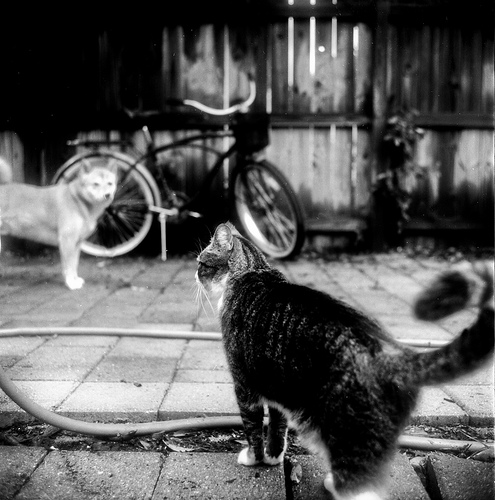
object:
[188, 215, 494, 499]
cat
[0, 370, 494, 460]
hose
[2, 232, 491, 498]
patio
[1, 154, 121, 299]
dog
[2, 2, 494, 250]
fence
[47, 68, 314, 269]
bike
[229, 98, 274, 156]
basket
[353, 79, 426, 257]
plant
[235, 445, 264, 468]
paw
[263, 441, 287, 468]
paw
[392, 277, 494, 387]
tail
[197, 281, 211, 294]
chin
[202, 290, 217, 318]
whiskers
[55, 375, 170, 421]
brick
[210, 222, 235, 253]
ear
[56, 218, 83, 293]
front leg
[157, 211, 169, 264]
kickstand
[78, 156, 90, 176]
ear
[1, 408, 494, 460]
hole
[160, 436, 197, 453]
leaf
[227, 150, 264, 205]
fender